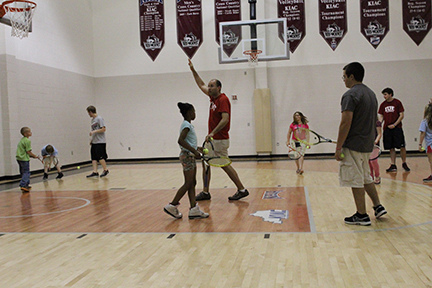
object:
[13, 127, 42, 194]
boy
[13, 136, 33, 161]
green shirt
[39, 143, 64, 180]
kid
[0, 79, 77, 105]
wall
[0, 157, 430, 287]
court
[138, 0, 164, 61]
banner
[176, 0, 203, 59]
banner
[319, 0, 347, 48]
banner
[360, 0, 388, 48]
banner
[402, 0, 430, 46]
banner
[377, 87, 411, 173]
person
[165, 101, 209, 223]
person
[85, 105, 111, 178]
person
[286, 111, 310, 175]
person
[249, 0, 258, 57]
pole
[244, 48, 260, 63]
basketball goal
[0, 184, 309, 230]
square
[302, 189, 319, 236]
lines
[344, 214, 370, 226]
tennis shoes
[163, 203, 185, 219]
tennis shoes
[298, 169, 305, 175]
tennis shoes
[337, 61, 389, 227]
man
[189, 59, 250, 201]
man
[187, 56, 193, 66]
hand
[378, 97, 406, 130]
shirt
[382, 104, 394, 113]
writing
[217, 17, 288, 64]
basketball hoop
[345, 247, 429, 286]
floor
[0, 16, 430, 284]
basketball court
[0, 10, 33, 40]
basketball netting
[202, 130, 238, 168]
shorts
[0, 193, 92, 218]
lines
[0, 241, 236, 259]
wood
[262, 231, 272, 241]
line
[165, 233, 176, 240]
line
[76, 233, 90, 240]
line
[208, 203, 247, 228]
sports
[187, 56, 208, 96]
up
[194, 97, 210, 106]
raised